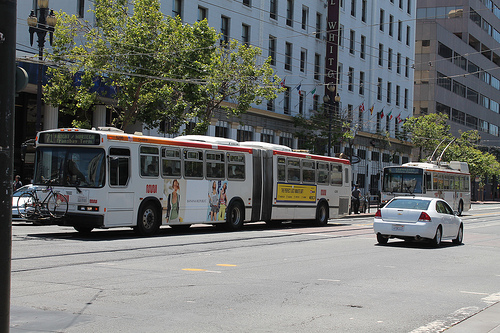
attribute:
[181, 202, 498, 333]
street — empty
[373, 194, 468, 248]
car — white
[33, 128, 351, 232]
bus — white, blue, extralong, advertising, normal, going